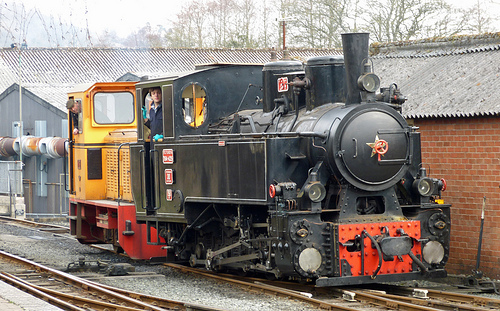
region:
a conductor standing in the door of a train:
[138, 85, 163, 151]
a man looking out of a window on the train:
[65, 96, 80, 131]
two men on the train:
[65, 85, 160, 132]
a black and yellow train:
[62, 30, 447, 285]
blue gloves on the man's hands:
[136, 105, 156, 140]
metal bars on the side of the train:
[115, 140, 160, 205]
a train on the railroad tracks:
[60, 30, 495, 306]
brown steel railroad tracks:
[0, 245, 97, 306]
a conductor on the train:
[136, 85, 162, 165]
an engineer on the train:
[64, 98, 82, 136]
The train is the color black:
[164, 81, 394, 193]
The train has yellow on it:
[75, 120, 128, 194]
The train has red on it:
[79, 200, 156, 259]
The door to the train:
[136, 75, 168, 217]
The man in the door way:
[138, 83, 173, 212]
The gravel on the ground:
[13, 227, 313, 309]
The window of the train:
[173, 79, 213, 134]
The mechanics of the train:
[159, 206, 281, 276]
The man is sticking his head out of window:
[65, 91, 90, 137]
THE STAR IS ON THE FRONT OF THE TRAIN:
[365, 131, 383, 161]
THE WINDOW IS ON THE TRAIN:
[86, 90, 134, 126]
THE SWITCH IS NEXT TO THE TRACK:
[463, 188, 495, 298]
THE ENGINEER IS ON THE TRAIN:
[140, 85, 170, 163]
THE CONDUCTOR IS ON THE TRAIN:
[63, 92, 84, 142]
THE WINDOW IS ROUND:
[175, 75, 211, 140]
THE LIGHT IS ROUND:
[360, 61, 380, 97]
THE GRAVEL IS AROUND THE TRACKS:
[0, 215, 497, 310]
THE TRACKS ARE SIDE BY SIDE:
[0, 207, 497, 307]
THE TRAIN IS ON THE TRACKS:
[41, 20, 482, 303]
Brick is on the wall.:
[407, 118, 497, 288]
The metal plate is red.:
[338, 221, 425, 273]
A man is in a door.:
[136, 83, 168, 215]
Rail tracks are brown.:
[2, 242, 499, 309]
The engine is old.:
[68, 51, 454, 293]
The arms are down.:
[173, 220, 275, 280]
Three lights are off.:
[303, 73, 430, 199]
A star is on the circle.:
[330, 102, 423, 189]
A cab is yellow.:
[64, 81, 129, 205]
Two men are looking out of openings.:
[63, 84, 181, 132]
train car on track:
[51, 79, 452, 289]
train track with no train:
[23, 265, 110, 303]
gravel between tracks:
[147, 273, 200, 294]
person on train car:
[143, 87, 173, 162]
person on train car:
[56, 89, 94, 132]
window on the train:
[94, 94, 126, 119]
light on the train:
[296, 237, 459, 274]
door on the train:
[135, 94, 167, 217]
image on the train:
[364, 131, 392, 166]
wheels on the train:
[174, 243, 249, 275]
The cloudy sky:
[2, 5, 497, 50]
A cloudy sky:
[3, 3, 498, 50]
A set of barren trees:
[4, 0, 499, 44]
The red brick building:
[364, 37, 498, 272]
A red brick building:
[371, 33, 497, 284]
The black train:
[58, 35, 468, 299]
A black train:
[56, 27, 438, 292]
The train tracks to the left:
[3, 234, 217, 307]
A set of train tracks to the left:
[2, 234, 205, 309]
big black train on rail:
[70, 95, 392, 259]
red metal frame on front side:
[340, 220, 430, 280]